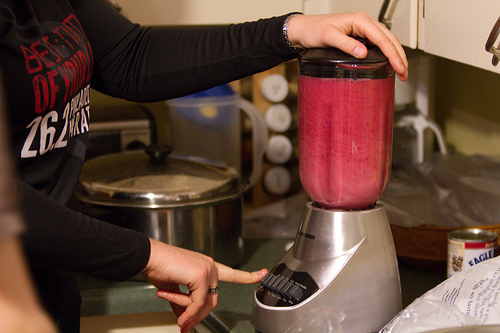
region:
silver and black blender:
[244, 50, 400, 330]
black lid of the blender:
[294, 43, 394, 73]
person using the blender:
[2, 3, 416, 317]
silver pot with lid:
[82, 125, 250, 267]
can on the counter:
[440, 225, 492, 284]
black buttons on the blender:
[250, 270, 300, 299]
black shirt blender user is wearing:
[5, 0, 281, 295]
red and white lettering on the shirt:
[16, 18, 97, 152]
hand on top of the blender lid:
[286, 12, 411, 73]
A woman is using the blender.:
[0, 0, 410, 331]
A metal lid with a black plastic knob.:
[80, 143, 240, 202]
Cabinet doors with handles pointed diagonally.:
[301, 0, 498, 75]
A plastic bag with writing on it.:
[379, 257, 499, 332]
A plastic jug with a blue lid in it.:
[167, 83, 268, 192]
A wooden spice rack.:
[240, 63, 290, 205]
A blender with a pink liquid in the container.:
[253, 48, 401, 332]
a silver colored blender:
[250, 49, 405, 331]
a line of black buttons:
[258, 270, 300, 297]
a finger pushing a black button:
[216, 263, 274, 283]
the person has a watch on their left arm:
[3, 0, 409, 331]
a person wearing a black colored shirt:
[3, 0, 411, 327]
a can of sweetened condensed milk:
[444, 225, 493, 272]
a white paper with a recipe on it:
[383, 252, 498, 330]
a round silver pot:
[81, 145, 246, 265]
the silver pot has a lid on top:
[78, 138, 244, 266]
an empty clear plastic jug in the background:
[163, 83, 263, 190]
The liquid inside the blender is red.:
[290, 59, 396, 206]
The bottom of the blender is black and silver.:
[247, 205, 411, 330]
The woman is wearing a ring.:
[142, 248, 259, 331]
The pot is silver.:
[81, 135, 265, 267]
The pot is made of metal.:
[78, 134, 258, 262]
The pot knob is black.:
[145, 133, 170, 165]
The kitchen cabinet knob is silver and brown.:
[483, 18, 498, 61]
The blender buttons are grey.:
[250, 270, 306, 299]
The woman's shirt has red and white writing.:
[12, 12, 122, 164]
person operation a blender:
[213, 15, 404, 332]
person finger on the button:
[207, 253, 267, 288]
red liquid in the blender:
[298, 63, 393, 212]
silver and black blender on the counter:
[223, 0, 402, 329]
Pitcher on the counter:
[168, 85, 275, 212]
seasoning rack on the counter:
[257, 66, 299, 205]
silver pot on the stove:
[85, 127, 251, 271]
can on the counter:
[444, 223, 494, 282]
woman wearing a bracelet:
[271, 11, 300, 46]